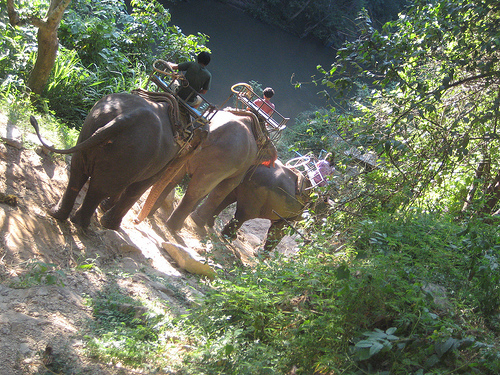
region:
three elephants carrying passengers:
[24, 40, 340, 270]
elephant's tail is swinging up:
[21, 100, 130, 185]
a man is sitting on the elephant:
[163, 40, 220, 128]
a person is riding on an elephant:
[305, 143, 345, 198]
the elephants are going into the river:
[32, 5, 382, 255]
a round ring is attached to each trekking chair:
[148, 55, 312, 172]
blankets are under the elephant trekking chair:
[127, 82, 187, 139]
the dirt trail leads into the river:
[20, 113, 303, 285]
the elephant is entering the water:
[240, 148, 337, 268]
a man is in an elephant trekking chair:
[146, 51, 221, 126]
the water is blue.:
[160, 2, 365, 140]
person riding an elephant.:
[229, 82, 284, 125]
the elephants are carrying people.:
[37, 45, 362, 243]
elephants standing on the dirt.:
[30, 39, 362, 260]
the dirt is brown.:
[0, 134, 262, 372]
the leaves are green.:
[5, 0, 217, 118]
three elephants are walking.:
[49, 73, 329, 245]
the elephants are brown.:
[45, 72, 325, 255]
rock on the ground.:
[154, 232, 222, 279]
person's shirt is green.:
[169, 47, 216, 101]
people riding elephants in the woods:
[23, 15, 348, 295]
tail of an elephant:
[25, 96, 126, 166]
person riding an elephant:
[171, 44, 221, 114]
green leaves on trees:
[232, 251, 494, 373]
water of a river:
[211, 17, 319, 80]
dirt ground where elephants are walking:
[16, 147, 51, 264]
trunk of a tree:
[21, 2, 74, 107]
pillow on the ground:
[160, 232, 220, 287]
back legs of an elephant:
[37, 167, 106, 232]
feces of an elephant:
[2, 180, 21, 218]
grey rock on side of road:
[156, 239, 217, 279]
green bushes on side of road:
[237, 299, 331, 354]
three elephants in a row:
[52, 87, 300, 245]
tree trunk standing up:
[0, 3, 53, 105]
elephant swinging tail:
[1, 124, 98, 179]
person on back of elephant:
[147, 45, 208, 131]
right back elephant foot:
[75, 199, 100, 241]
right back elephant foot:
[167, 203, 187, 232]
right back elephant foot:
[221, 217, 242, 249]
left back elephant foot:
[41, 187, 71, 219]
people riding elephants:
[37, 28, 329, 258]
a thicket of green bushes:
[330, 230, 415, 354]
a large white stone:
[162, 231, 238, 287]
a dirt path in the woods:
[16, 160, 51, 214]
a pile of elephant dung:
[0, 188, 24, 211]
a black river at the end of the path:
[225, 36, 279, 78]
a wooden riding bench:
[231, 80, 291, 127]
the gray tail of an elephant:
[23, 111, 91, 160]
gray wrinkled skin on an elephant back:
[214, 131, 233, 166]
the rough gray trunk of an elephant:
[147, 174, 160, 224]